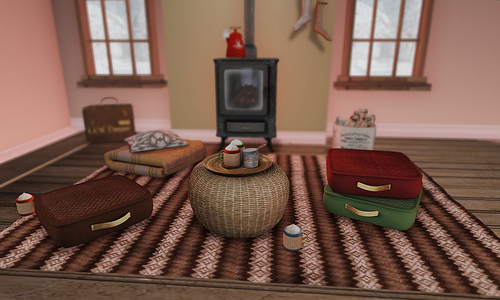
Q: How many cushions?
A: Four.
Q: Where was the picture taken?
A: Living room.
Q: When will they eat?
A: Now.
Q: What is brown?
A: Cushion.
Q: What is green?
A: Seat.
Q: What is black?
A: Stove.